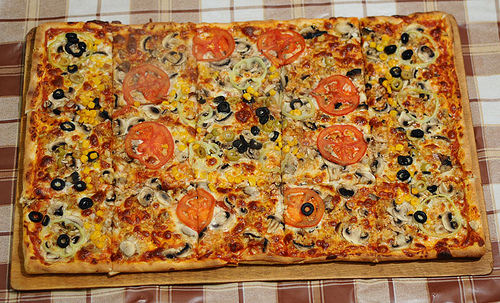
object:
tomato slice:
[257, 27, 306, 68]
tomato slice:
[309, 73, 360, 116]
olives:
[213, 95, 281, 153]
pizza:
[18, 10, 489, 277]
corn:
[79, 47, 115, 250]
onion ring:
[228, 56, 269, 91]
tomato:
[317, 124, 369, 165]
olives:
[49, 178, 93, 210]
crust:
[21, 246, 487, 275]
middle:
[195, 95, 282, 183]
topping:
[223, 170, 243, 183]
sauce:
[439, 58, 453, 94]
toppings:
[38, 30, 437, 239]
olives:
[382, 32, 415, 79]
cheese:
[292, 156, 313, 173]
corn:
[242, 86, 259, 101]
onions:
[39, 219, 84, 257]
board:
[5, 13, 494, 291]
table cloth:
[0, 0, 500, 303]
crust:
[21, 23, 47, 275]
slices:
[18, 21, 113, 276]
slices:
[111, 22, 197, 272]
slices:
[280, 16, 376, 264]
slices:
[360, 10, 488, 263]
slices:
[19, 179, 488, 276]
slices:
[23, 9, 463, 113]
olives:
[394, 155, 412, 182]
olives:
[63, 32, 87, 58]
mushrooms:
[341, 223, 414, 250]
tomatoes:
[176, 187, 324, 232]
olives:
[27, 197, 94, 248]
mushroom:
[417, 195, 470, 237]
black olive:
[213, 94, 232, 114]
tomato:
[125, 121, 175, 171]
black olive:
[64, 32, 89, 58]